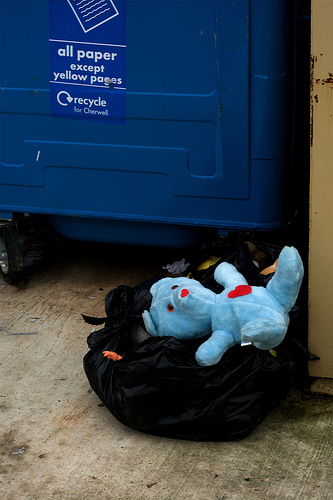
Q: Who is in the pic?
A: A doll.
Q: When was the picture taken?
A: During the day.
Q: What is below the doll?
A: Garbage.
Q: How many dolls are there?
A: 1.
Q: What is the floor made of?
A: Stone.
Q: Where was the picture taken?
A: Near the trash bin.